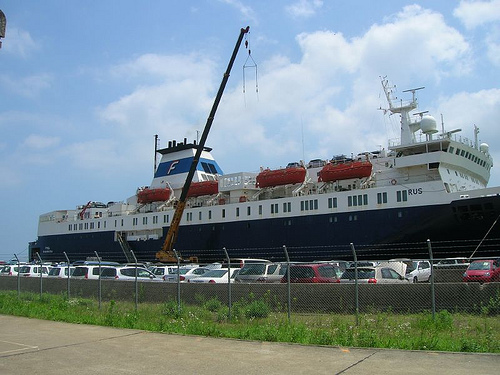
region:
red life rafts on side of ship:
[322, 153, 389, 189]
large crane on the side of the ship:
[137, 22, 265, 276]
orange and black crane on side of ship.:
[139, 2, 254, 249]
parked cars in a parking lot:
[13, 261, 447, 294]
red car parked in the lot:
[279, 253, 351, 303]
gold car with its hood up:
[342, 258, 417, 293]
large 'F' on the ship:
[148, 154, 210, 190]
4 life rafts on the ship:
[120, 155, 387, 205]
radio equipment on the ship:
[355, 53, 466, 218]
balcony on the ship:
[209, 165, 288, 234]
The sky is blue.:
[59, 10, 162, 45]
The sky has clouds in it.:
[95, 13, 184, 97]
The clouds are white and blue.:
[276, 11, 425, 73]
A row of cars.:
[12, 253, 464, 295]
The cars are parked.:
[5, 253, 495, 298]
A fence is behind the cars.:
[5, 247, 493, 315]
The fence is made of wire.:
[7, 242, 497, 319]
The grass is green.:
[145, 307, 424, 338]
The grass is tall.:
[119, 287, 481, 346]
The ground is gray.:
[136, 346, 214, 371]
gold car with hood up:
[335, 259, 413, 298]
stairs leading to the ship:
[108, 225, 144, 276]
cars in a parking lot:
[9, 258, 494, 301]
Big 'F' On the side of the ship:
[142, 146, 226, 186]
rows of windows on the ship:
[55, 203, 426, 237]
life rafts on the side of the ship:
[121, 163, 398, 201]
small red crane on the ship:
[70, 194, 111, 234]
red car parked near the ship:
[277, 246, 370, 324]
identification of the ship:
[397, 179, 453, 214]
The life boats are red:
[101, 155, 399, 222]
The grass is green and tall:
[51, 300, 327, 355]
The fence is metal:
[61, 234, 425, 347]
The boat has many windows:
[71, 186, 466, 222]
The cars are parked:
[70, 250, 432, 312]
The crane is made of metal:
[148, 55, 223, 283]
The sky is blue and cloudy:
[50, 64, 196, 151]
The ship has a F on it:
[144, 124, 202, 183]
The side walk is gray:
[25, 325, 102, 368]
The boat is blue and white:
[63, 127, 415, 363]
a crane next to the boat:
[154, 27, 249, 252]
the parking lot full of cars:
[6, 259, 496, 282]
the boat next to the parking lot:
[40, 113, 494, 279]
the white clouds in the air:
[116, 17, 493, 159]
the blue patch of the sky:
[8, 13, 146, 181]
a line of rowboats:
[127, 151, 366, 214]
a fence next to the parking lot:
[2, 246, 499, 347]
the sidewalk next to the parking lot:
[0, 312, 498, 374]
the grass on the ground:
[15, 283, 497, 353]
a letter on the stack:
[158, 157, 185, 175]